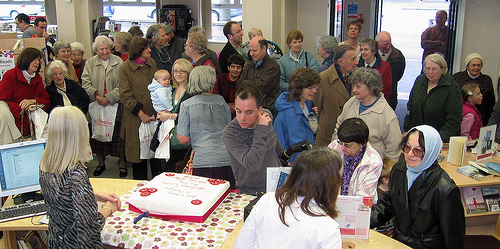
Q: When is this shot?
A: Daytime.